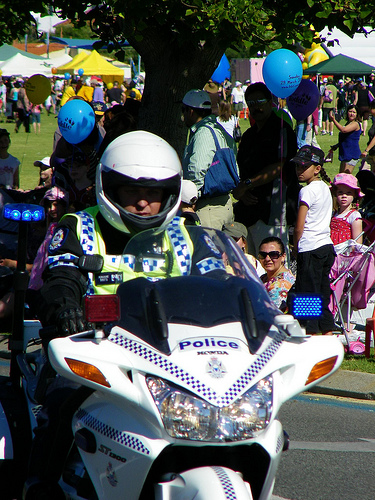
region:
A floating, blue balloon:
[262, 49, 302, 99]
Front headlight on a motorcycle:
[154, 386, 264, 441]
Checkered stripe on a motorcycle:
[109, 333, 280, 404]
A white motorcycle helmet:
[97, 129, 181, 237]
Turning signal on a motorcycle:
[64, 354, 110, 388]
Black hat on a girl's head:
[290, 143, 323, 166]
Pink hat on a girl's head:
[330, 173, 363, 197]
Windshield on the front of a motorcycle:
[117, 227, 275, 320]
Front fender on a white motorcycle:
[154, 464, 253, 499]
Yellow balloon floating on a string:
[25, 73, 52, 105]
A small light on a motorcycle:
[305, 355, 337, 386]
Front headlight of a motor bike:
[145, 373, 274, 445]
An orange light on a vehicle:
[64, 356, 110, 389]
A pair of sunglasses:
[258, 249, 285, 260]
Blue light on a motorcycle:
[288, 290, 324, 317]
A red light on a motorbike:
[81, 293, 121, 322]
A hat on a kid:
[288, 144, 323, 165]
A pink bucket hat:
[330, 172, 365, 198]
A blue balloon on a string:
[261, 48, 302, 237]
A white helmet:
[95, 129, 183, 237]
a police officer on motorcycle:
[0, 131, 347, 492]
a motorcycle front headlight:
[147, 372, 273, 442]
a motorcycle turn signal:
[63, 355, 109, 386]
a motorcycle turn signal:
[305, 355, 338, 384]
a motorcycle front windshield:
[117, 226, 262, 288]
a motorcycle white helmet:
[93, 129, 182, 236]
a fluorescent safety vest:
[58, 201, 191, 296]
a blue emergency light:
[292, 294, 320, 318]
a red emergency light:
[84, 295, 118, 321]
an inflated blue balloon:
[56, 98, 94, 146]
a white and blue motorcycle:
[28, 312, 349, 498]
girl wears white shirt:
[288, 141, 336, 303]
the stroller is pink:
[325, 227, 370, 363]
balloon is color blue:
[259, 40, 306, 126]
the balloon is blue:
[52, 90, 100, 160]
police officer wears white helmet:
[32, 120, 240, 295]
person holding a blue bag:
[176, 87, 244, 222]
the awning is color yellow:
[69, 46, 129, 87]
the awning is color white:
[3, 51, 50, 77]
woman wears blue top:
[324, 99, 366, 176]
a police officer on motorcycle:
[22, 120, 352, 496]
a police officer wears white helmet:
[32, 117, 246, 306]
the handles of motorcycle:
[12, 308, 355, 406]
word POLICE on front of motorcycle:
[171, 330, 248, 356]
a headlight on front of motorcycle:
[140, 367, 283, 450]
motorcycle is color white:
[25, 315, 351, 498]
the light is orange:
[303, 350, 342, 389]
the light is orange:
[58, 351, 115, 393]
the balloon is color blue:
[257, 40, 308, 122]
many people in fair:
[0, 11, 373, 187]